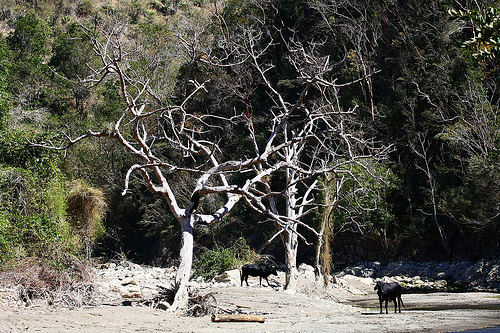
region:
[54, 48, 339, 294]
tree is white and bare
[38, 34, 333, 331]
tree is leave-less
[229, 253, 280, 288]
black bull by dead tree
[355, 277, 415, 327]
black bull in grey dirt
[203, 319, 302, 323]
brown log by white tree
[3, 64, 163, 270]
greenery behind white tree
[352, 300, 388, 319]
shadow cast by bull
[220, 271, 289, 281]
black bull standing by white tree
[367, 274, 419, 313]
bull with swaying tail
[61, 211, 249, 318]
shadows cast by tree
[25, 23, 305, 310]
a gnarled large white bare tree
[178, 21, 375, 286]
a gnarled large white bare tree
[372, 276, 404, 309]
a sleek black water buffalo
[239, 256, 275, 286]
a sleek black water buffalo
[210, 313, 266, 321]
a tan dead log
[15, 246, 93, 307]
a pile of gray sticks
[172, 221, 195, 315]
a white tree trunk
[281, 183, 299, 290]
a white tree trunk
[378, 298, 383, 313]
the black leg of the animal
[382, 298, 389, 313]
the black leg of the animal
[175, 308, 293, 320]
the log is under the tree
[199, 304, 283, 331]
the log is under the tree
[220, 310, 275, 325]
the log is under the tree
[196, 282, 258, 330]
the log is under the tree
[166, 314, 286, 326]
the log is under the tree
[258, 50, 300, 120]
part of some branches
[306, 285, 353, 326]
part of a ground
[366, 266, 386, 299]
head of a cow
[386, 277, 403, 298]
stomach of a cow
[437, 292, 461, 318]
part of a shore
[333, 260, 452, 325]
the cow is black